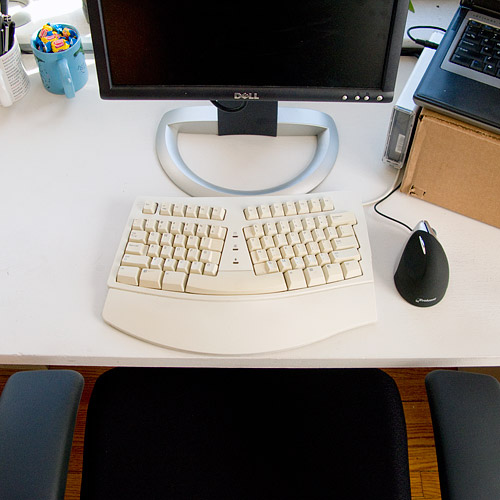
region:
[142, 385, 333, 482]
The seat of the chair is black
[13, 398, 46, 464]
arms of chair is blue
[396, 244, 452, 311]
a black mouse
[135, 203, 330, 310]
the keyboard is white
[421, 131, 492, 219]
a box on the table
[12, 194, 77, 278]
the table is white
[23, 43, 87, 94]
a blue cup on table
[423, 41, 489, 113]
a laptop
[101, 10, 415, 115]
computer screen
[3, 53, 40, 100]
a white cup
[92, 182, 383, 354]
This is a keyboard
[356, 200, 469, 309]
A mouse beside the keyboard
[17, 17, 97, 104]
Gum is inside of the cub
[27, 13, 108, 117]
The cup is blue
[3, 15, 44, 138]
The markers are black and white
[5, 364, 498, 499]
This is a chair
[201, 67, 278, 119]
"Dell" on the monitor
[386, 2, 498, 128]
Another laptop is in the picture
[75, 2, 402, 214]
This monitor is black and silver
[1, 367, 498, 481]
The floor is made of wood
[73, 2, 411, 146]
a dell monitor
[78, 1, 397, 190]
a black monitor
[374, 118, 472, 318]
a black mouse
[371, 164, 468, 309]
a black mouse with a cord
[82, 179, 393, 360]
a computer keyboard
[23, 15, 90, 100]
a blue mug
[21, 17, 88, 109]
a mug filled with goodies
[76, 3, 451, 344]
a desktop computer sitting on a white desk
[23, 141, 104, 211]
a white desk for the desktop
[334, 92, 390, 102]
control buttons of the monitor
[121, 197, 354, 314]
A keyboard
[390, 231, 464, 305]
A black mouse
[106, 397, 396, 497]
The seat of a chair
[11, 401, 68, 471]
The arms of the chair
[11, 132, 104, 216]
A white desk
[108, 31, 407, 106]
A desktop screen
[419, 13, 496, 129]
keyboard of a laptop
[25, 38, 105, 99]
A blue cup on table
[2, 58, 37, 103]
A white cup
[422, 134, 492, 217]
a brown box on the table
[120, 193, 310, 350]
white keyboard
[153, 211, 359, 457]
white keyboard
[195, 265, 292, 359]
white keyboard